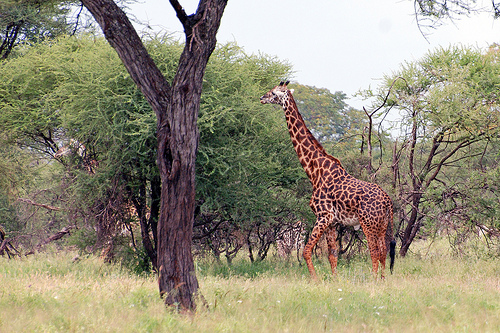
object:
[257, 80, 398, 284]
giraffe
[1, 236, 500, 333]
field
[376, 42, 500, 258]
tree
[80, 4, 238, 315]
tree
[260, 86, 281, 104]
face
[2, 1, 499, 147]
sky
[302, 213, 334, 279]
leg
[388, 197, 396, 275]
tail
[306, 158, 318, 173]
spot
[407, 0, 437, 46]
branch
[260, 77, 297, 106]
head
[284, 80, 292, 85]
ossicones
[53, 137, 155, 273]
giraffe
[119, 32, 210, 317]
tree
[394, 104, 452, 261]
trunk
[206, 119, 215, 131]
leaf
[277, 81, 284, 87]
ear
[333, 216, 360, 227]
under belly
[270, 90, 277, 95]
lashes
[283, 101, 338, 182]
neck